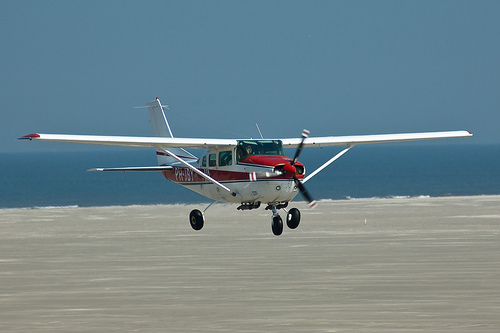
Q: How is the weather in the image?
A: It is clear.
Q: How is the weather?
A: It is clear.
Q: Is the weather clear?
A: Yes, it is clear.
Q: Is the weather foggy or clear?
A: It is clear.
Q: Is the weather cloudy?
A: No, it is clear.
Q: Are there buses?
A: No, there are no buses.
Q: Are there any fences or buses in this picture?
A: No, there are no buses or fences.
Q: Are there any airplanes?
A: Yes, there is an airplane.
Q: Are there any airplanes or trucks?
A: Yes, there is an airplane.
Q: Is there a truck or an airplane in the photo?
A: Yes, there is an airplane.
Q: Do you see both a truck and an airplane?
A: No, there is an airplane but no trucks.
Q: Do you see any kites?
A: No, there are no kites.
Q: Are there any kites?
A: No, there are no kites.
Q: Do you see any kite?
A: No, there are no kites.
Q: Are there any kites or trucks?
A: No, there are no kites or trucks.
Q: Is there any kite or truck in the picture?
A: No, there are no kites or trucks.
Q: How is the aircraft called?
A: The aircraft is an airplane.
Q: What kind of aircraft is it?
A: The aircraft is an airplane.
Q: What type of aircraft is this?
A: This is an airplane.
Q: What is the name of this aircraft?
A: This is an airplane.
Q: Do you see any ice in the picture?
A: Yes, there is ice.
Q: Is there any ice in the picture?
A: Yes, there is ice.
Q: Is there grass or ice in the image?
A: Yes, there is ice.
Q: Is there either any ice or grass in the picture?
A: Yes, there is ice.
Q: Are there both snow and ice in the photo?
A: No, there is ice but no snow.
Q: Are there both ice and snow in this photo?
A: No, there is ice but no snow.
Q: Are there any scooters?
A: No, there are no scooters.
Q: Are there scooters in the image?
A: No, there are no scooters.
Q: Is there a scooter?
A: No, there are no scooters.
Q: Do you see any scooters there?
A: No, there are no scooters.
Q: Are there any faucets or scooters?
A: No, there are no scooters or faucets.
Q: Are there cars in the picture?
A: No, there are no cars.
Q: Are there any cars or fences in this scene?
A: No, there are no cars or fences.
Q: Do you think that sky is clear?
A: Yes, the sky is clear.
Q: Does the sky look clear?
A: Yes, the sky is clear.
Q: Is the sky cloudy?
A: No, the sky is clear.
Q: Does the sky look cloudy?
A: No, the sky is clear.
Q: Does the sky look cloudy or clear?
A: The sky is clear.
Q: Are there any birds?
A: No, there are no birds.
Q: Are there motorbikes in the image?
A: No, there are no motorbikes.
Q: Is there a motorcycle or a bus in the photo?
A: No, there are no motorcycles or buses.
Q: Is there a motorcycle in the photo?
A: No, there are no motorcycles.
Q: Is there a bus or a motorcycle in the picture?
A: No, there are no motorcycles or buses.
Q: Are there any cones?
A: No, there are no cones.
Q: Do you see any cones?
A: No, there are no cones.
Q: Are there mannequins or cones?
A: No, there are no cones or mannequins.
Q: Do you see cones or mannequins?
A: No, there are no cones or mannequins.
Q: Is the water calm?
A: Yes, the water is calm.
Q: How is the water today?
A: The water is calm.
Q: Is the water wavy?
A: No, the water is calm.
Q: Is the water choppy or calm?
A: The water is calm.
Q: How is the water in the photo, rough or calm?
A: The water is calm.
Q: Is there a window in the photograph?
A: Yes, there are windows.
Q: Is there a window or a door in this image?
A: Yes, there are windows.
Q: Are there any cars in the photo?
A: No, there are no cars.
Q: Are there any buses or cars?
A: No, there are no cars or buses.